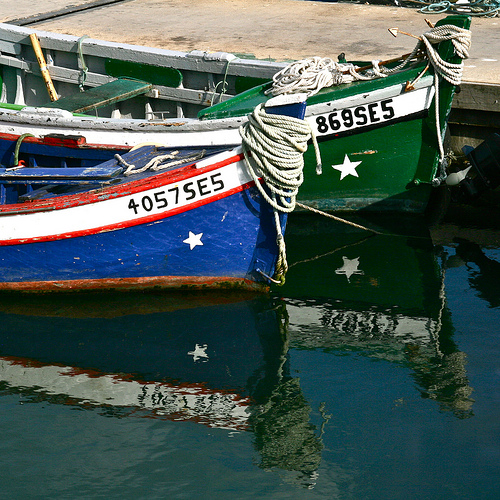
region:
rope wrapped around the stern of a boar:
[241, 100, 300, 208]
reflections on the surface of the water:
[93, 317, 415, 447]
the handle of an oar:
[19, 31, 63, 94]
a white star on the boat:
[166, 219, 223, 254]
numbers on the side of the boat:
[118, 167, 225, 216]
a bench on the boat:
[61, 75, 163, 115]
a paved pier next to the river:
[119, 14, 384, 46]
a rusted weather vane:
[390, 14, 437, 96]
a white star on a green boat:
[319, 154, 382, 196]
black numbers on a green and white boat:
[312, 96, 407, 138]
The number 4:
[128, 197, 139, 215]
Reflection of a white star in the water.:
[188, 342, 210, 362]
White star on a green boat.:
[332, 151, 363, 180]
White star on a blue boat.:
[182, 232, 202, 248]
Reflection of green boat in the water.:
[268, 206, 473, 418]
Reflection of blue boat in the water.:
[1, 283, 317, 491]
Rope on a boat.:
[237, 106, 323, 267]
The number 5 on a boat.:
[209, 173, 224, 190]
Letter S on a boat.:
[353, 105, 366, 126]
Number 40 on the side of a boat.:
[125, 193, 153, 215]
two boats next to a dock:
[0, 15, 471, 335]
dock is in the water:
[1, 1, 498, 126]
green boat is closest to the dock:
[1, 16, 481, 213]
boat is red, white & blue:
[2, 90, 313, 302]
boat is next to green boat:
[5, 123, 312, 315]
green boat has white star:
[332, 151, 361, 182]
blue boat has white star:
[180, 229, 207, 252]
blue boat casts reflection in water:
[7, 285, 284, 456]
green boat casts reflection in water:
[285, 205, 454, 345]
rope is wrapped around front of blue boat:
[247, 90, 300, 290]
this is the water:
[310, 333, 432, 495]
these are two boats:
[8, 43, 446, 290]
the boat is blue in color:
[121, 230, 162, 282]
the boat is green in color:
[373, 140, 418, 186]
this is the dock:
[239, 4, 396, 45]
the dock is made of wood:
[230, 3, 365, 40]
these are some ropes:
[253, 52, 368, 190]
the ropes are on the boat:
[281, 61, 368, 92]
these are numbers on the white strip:
[122, 190, 167, 211]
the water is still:
[276, 343, 399, 439]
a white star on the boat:
[329, 150, 363, 186]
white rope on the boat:
[239, 100, 307, 285]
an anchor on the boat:
[384, 15, 447, 94]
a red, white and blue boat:
[1, 86, 317, 295]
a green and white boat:
[0, 12, 473, 215]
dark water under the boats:
[1, 206, 497, 498]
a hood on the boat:
[251, 257, 285, 287]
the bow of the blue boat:
[237, 88, 314, 293]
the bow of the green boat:
[399, 10, 476, 212]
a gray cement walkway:
[0, 0, 499, 112]